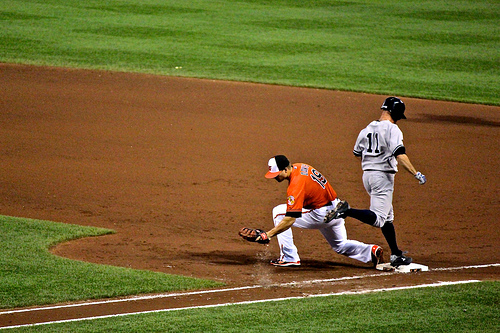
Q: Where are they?
A: On the field.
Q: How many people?
A: 2.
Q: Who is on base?
A: The player.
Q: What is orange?
A: The jersey.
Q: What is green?
A: The grass.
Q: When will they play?
A: Now.